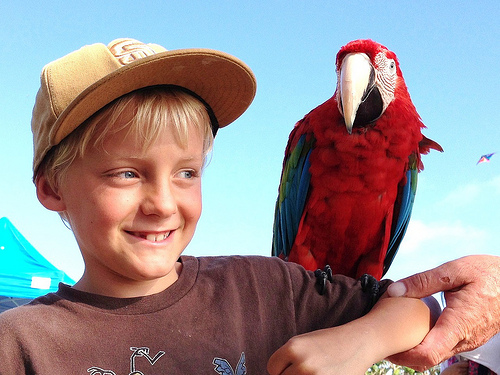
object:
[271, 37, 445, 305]
parrot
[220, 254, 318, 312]
shoulder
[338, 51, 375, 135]
beak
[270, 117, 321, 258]
wing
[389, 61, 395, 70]
eye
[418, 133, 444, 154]
feather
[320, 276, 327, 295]
talon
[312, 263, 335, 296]
foot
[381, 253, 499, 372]
hand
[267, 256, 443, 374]
arm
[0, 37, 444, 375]
kid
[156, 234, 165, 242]
front tooth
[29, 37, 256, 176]
baseball cap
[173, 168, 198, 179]
eye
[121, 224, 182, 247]
mouth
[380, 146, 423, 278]
left wing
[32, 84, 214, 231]
hair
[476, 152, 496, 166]
kite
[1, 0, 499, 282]
sky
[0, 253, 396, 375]
shirt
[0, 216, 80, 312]
tent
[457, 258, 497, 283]
cut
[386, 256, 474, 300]
thumb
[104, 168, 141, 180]
eye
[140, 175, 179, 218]
nose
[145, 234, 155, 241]
front tooth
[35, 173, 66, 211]
left ear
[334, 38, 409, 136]
head